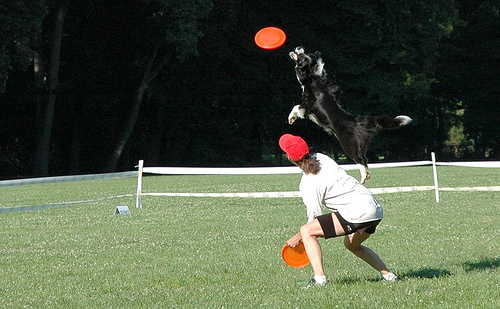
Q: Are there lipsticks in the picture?
A: No, there are no lipsticks.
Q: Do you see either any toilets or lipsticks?
A: No, there are no lipsticks or toilets.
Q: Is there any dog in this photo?
A: Yes, there is a dog.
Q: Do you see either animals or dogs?
A: Yes, there is a dog.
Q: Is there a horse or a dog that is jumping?
A: Yes, the dog is jumping.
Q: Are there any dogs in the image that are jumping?
A: Yes, there is a dog that is jumping.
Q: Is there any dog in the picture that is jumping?
A: Yes, there is a dog that is jumping.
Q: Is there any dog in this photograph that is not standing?
A: Yes, there is a dog that is jumping.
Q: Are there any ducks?
A: No, there are no ducks.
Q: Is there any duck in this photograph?
A: No, there are no ducks.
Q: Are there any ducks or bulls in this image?
A: No, there are no ducks or bulls.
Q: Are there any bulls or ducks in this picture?
A: No, there are no ducks or bulls.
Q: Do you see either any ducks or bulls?
A: No, there are no ducks or bulls.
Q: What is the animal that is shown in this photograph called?
A: The animal is a dog.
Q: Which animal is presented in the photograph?
A: The animal is a dog.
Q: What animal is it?
A: The animal is a dog.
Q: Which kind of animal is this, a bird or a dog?
A: That is a dog.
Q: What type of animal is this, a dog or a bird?
A: That is a dog.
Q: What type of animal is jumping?
A: The animal is a dog.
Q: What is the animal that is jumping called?
A: The animal is a dog.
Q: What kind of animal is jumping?
A: The animal is a dog.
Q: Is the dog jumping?
A: Yes, the dog is jumping.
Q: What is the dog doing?
A: The dog is jumping.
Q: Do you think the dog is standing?
A: No, the dog is jumping.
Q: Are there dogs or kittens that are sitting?
A: No, there is a dog but it is jumping.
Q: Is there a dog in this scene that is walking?
A: No, there is a dog but it is jumping.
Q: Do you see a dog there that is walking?
A: No, there is a dog but it is jumping.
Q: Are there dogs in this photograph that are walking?
A: No, there is a dog but it is jumping.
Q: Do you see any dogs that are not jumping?
A: No, there is a dog but it is jumping.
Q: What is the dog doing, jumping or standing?
A: The dog is jumping.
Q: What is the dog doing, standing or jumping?
A: The dog is jumping.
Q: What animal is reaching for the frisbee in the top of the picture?
A: The animal is a dog.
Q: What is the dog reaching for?
A: The dog is reaching for the frisbee.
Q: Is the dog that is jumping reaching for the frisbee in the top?
A: Yes, the dog is reaching for the frisbee.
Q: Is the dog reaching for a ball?
A: No, the dog is reaching for the frisbee.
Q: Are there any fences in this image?
A: Yes, there is a fence.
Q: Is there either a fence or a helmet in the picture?
A: Yes, there is a fence.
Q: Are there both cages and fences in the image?
A: No, there is a fence but no cages.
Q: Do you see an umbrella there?
A: No, there are no umbrellas.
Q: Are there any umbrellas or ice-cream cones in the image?
A: No, there are no umbrellas or ice-cream cones.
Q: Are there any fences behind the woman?
A: Yes, there is a fence behind the woman.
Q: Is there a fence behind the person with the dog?
A: Yes, there is a fence behind the woman.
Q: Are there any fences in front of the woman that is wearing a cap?
A: No, the fence is behind the woman.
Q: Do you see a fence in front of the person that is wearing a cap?
A: No, the fence is behind the woman.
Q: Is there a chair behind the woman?
A: No, there is a fence behind the woman.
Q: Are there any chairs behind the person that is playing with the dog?
A: No, there is a fence behind the woman.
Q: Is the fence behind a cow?
A: No, the fence is behind the woman.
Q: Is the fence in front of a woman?
A: No, the fence is behind a woman.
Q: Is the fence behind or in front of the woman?
A: The fence is behind the woman.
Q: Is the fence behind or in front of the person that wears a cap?
A: The fence is behind the woman.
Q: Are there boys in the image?
A: No, there are no boys.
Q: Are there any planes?
A: No, there are no planes.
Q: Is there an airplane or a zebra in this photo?
A: No, there are no airplanes or zebras.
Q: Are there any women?
A: Yes, there is a woman.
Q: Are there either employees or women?
A: Yes, there is a woman.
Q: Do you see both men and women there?
A: No, there is a woman but no men.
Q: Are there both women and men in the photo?
A: No, there is a woman but no men.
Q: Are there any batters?
A: No, there are no batters.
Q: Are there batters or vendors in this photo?
A: No, there are no batters or vendors.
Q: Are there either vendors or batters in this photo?
A: No, there are no batters or vendors.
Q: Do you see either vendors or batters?
A: No, there are no batters or vendors.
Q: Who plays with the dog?
A: The woman plays with the dog.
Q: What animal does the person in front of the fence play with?
A: The woman plays with the dog.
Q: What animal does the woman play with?
A: The woman plays with the dog.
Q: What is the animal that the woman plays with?
A: The animal is a dog.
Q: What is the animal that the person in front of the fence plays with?
A: The animal is a dog.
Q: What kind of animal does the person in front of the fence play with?
A: The woman plays with the dog.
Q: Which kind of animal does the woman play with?
A: The woman plays with the dog.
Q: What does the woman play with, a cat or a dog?
A: The woman plays with a dog.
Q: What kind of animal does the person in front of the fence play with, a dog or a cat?
A: The woman plays with a dog.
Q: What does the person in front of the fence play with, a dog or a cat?
A: The woman plays with a dog.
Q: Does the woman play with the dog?
A: Yes, the woman plays with the dog.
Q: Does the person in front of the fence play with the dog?
A: Yes, the woman plays with the dog.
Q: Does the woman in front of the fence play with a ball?
A: No, the woman plays with the dog.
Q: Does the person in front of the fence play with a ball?
A: No, the woman plays with the dog.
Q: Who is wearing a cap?
A: The woman is wearing a cap.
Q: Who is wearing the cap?
A: The woman is wearing a cap.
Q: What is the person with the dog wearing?
A: The woman is wearing a cap.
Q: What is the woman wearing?
A: The woman is wearing a cap.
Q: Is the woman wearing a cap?
A: Yes, the woman is wearing a cap.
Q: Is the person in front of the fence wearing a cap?
A: Yes, the woman is wearing a cap.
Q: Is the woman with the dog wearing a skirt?
A: No, the woman is wearing a cap.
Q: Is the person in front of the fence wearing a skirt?
A: No, the woman is wearing a cap.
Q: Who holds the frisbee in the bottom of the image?
A: The woman holds the frisbee.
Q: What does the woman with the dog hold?
A: The woman holds the frisbee.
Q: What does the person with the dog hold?
A: The woman holds the frisbee.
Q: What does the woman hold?
A: The woman holds the frisbee.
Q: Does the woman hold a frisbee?
A: Yes, the woman holds a frisbee.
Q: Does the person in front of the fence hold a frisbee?
A: Yes, the woman holds a frisbee.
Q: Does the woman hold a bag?
A: No, the woman holds a frisbee.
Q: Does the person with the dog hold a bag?
A: No, the woman holds a frisbee.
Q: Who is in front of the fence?
A: The woman is in front of the fence.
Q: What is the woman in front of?
A: The woman is in front of the fence.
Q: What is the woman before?
A: The woman is in front of the fence.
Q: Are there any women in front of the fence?
A: Yes, there is a woman in front of the fence.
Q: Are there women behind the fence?
A: No, the woman is in front of the fence.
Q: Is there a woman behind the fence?
A: No, the woman is in front of the fence.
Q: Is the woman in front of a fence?
A: Yes, the woman is in front of a fence.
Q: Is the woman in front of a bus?
A: No, the woman is in front of a fence.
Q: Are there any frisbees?
A: Yes, there is a frisbee.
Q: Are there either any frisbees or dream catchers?
A: Yes, there is a frisbee.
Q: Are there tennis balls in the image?
A: No, there are no tennis balls.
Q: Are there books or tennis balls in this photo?
A: No, there are no tennis balls or books.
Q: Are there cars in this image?
A: No, there are no cars.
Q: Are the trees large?
A: Yes, the trees are large.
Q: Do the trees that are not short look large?
A: Yes, the trees are large.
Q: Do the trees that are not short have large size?
A: Yes, the trees are large.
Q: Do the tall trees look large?
A: Yes, the trees are large.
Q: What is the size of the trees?
A: The trees are large.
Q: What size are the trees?
A: The trees are large.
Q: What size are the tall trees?
A: The trees are large.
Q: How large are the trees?
A: The trees are large.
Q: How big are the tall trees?
A: The trees are large.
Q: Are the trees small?
A: No, the trees are large.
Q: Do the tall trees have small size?
A: No, the trees are large.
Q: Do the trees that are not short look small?
A: No, the trees are large.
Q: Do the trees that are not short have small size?
A: No, the trees are large.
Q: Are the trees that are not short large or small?
A: The trees are large.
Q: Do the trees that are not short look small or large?
A: The trees are large.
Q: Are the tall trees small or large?
A: The trees are large.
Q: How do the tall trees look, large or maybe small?
A: The trees are large.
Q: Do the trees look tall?
A: Yes, the trees are tall.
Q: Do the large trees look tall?
A: Yes, the trees are tall.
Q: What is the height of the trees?
A: The trees are tall.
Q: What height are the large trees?
A: The trees are tall.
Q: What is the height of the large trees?
A: The trees are tall.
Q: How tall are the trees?
A: The trees are tall.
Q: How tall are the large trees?
A: The trees are tall.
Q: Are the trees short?
A: No, the trees are tall.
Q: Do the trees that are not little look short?
A: No, the trees are tall.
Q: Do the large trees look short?
A: No, the trees are tall.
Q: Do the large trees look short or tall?
A: The trees are tall.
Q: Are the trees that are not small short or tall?
A: The trees are tall.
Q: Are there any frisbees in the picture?
A: Yes, there is a frisbee.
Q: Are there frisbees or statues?
A: Yes, there is a frisbee.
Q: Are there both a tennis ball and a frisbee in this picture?
A: No, there is a frisbee but no tennis balls.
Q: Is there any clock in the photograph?
A: No, there are no clocks.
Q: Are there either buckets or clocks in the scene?
A: No, there are no clocks or buckets.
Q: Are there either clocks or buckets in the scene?
A: No, there are no clocks or buckets.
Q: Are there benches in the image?
A: No, there are no benches.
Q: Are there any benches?
A: No, there are no benches.